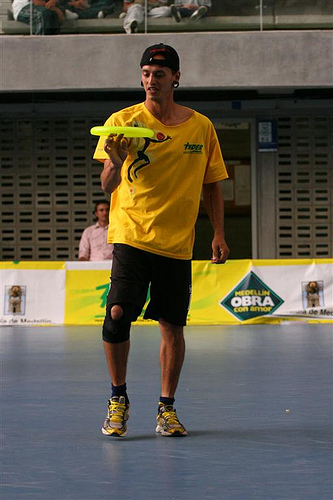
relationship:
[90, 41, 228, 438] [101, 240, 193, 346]
man wearing shorts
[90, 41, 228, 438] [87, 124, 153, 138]
man holding frisbee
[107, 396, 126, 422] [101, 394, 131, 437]
lace tying shoe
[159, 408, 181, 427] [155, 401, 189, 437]
lace tying shoe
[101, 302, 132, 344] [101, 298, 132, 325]
brace worn around knee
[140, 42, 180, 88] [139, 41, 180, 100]
cap worn on head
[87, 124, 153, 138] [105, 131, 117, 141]
frisbee balancing on finger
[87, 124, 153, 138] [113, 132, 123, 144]
frisbee balancing on finger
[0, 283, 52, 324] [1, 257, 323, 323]
logo printed on wall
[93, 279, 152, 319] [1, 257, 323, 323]
logo printed on wall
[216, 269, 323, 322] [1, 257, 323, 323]
logo printed on wall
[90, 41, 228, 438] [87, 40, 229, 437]
man performing trick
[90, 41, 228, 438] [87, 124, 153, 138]
man balancing frisbee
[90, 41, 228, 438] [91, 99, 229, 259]
man wearing shirt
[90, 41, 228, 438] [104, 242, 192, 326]
man wearing shorts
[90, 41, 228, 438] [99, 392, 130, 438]
man wearing shoe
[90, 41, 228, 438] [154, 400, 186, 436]
man wearing shoe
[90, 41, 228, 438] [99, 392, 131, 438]
man lifting foot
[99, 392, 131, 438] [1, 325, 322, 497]
foot hanging above ground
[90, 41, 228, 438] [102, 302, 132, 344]
man wearing brace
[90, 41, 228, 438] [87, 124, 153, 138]
man playing with frisbee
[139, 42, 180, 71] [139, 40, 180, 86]
back belonging to cap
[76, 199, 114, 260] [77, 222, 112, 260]
man wearing shirt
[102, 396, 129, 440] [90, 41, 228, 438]
shoe on man